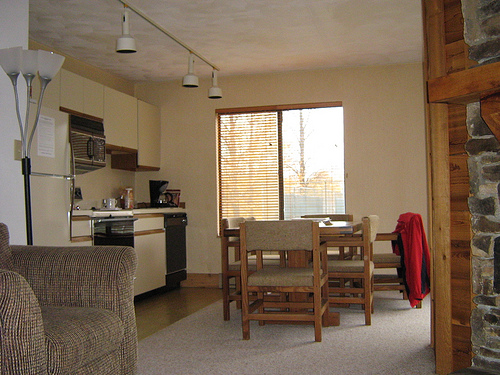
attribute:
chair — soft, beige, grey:
[0, 218, 139, 375]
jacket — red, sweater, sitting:
[392, 213, 430, 308]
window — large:
[216, 101, 348, 240]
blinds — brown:
[221, 106, 278, 220]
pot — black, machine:
[150, 180, 171, 207]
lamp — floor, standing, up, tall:
[2, 45, 67, 246]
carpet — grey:
[137, 288, 431, 375]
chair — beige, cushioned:
[239, 220, 328, 343]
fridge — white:
[27, 102, 77, 247]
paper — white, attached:
[35, 114, 59, 160]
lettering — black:
[39, 117, 55, 157]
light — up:
[2, 45, 67, 158]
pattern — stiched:
[2, 318, 43, 375]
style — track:
[111, 1, 225, 101]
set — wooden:
[217, 209, 428, 345]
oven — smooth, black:
[92, 215, 139, 248]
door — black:
[94, 219, 135, 248]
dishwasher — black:
[163, 213, 189, 290]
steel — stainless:
[70, 114, 105, 173]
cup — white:
[104, 198, 119, 209]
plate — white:
[101, 206, 125, 212]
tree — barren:
[222, 112, 276, 222]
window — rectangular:
[220, 112, 283, 227]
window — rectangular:
[280, 106, 346, 222]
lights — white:
[114, 37, 225, 100]